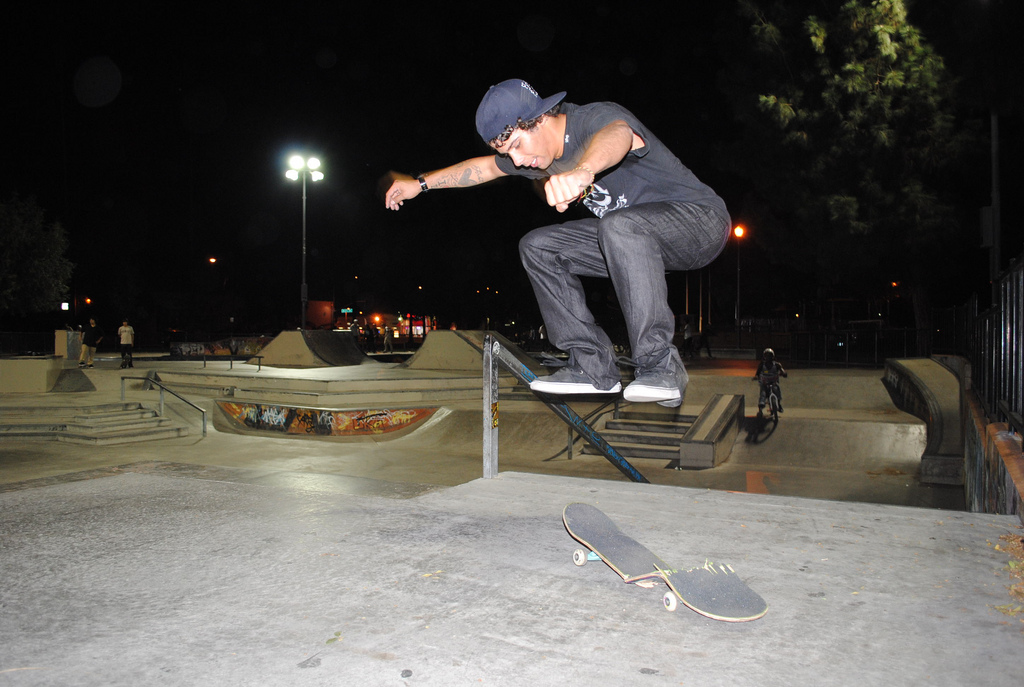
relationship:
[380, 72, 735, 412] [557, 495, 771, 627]
man jumping above skateboard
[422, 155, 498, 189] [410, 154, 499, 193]
forearm inked on forearm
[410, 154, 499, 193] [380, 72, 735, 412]
forearm belonging to man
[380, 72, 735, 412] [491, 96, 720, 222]
man wearing shirt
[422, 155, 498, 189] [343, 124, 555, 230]
forearm on arm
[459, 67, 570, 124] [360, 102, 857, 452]
hat on person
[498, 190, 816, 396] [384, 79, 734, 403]
pants on man